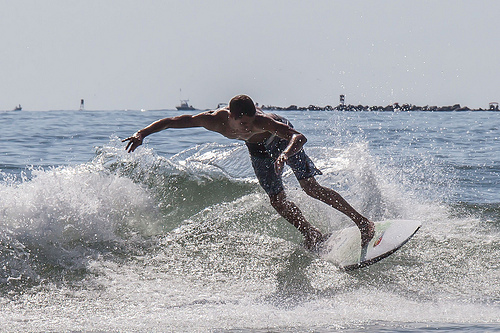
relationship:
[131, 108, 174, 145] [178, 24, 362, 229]
arm of surfer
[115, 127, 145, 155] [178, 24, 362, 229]
hand of surfer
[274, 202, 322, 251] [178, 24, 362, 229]
leg of surfer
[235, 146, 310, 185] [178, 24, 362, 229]
shorts on surfer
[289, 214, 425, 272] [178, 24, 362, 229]
surfboard under surfer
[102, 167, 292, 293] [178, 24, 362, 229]
waves under surfer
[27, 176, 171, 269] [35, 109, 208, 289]
wave in ocean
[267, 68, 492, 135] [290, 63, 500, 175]
island across water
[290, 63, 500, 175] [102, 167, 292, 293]
water has waves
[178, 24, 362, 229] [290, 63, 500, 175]
surfer in water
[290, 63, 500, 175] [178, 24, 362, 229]
water by surfer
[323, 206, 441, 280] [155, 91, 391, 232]
board under man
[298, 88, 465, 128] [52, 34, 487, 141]
land in background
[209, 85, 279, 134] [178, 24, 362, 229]
head of surfer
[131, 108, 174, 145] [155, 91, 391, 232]
arm of man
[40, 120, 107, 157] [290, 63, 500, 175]
ripples on water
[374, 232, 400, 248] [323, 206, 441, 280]
design on board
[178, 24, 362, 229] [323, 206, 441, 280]
surfer on board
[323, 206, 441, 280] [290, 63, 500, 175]
board in water